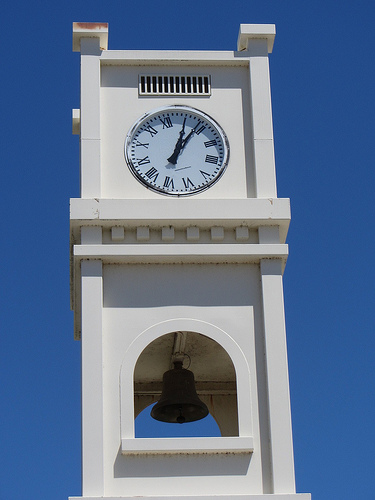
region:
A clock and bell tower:
[61, 17, 313, 499]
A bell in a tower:
[148, 357, 212, 426]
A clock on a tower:
[121, 102, 232, 196]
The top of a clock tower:
[66, 17, 279, 135]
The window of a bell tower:
[116, 315, 257, 458]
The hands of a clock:
[165, 113, 204, 167]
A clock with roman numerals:
[121, 102, 231, 197]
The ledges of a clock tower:
[66, 197, 294, 261]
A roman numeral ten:
[134, 138, 151, 151]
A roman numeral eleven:
[140, 122, 160, 138]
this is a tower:
[103, 259, 263, 313]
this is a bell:
[148, 372, 205, 420]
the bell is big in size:
[150, 362, 208, 419]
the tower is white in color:
[171, 271, 249, 314]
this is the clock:
[123, 105, 228, 195]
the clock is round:
[118, 98, 230, 192]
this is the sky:
[285, 64, 372, 146]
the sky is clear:
[316, 251, 372, 309]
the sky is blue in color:
[302, 293, 368, 359]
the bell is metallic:
[151, 362, 207, 423]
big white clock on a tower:
[112, 99, 235, 201]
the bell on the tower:
[146, 346, 224, 437]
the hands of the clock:
[160, 111, 208, 163]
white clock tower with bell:
[38, 16, 320, 429]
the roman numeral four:
[201, 148, 224, 163]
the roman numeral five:
[194, 167, 217, 186]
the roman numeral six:
[180, 172, 195, 189]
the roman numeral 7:
[156, 172, 177, 195]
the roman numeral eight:
[143, 163, 159, 186]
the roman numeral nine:
[135, 151, 158, 171]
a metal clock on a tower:
[123, 102, 232, 196]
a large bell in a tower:
[146, 353, 208, 423]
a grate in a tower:
[135, 69, 212, 95]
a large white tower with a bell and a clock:
[69, 10, 310, 499]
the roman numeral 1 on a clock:
[180, 115, 188, 126]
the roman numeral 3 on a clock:
[201, 139, 218, 147]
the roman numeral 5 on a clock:
[196, 167, 209, 180]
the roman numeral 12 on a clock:
[159, 116, 172, 128]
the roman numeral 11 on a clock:
[144, 124, 157, 137]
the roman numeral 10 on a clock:
[133, 139, 150, 149]